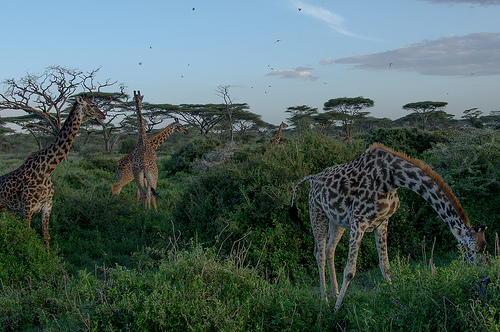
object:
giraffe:
[288, 139, 499, 314]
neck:
[401, 151, 474, 225]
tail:
[286, 173, 309, 210]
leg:
[370, 230, 397, 286]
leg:
[332, 223, 368, 311]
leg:
[324, 225, 345, 292]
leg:
[309, 222, 330, 299]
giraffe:
[109, 117, 189, 196]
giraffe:
[131, 88, 161, 211]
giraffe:
[1, 86, 128, 255]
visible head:
[75, 90, 108, 122]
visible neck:
[45, 109, 84, 167]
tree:
[1, 63, 128, 159]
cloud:
[319, 32, 499, 75]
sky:
[1, 2, 499, 82]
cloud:
[260, 64, 324, 92]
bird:
[273, 37, 286, 48]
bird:
[295, 4, 306, 17]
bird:
[188, 5, 198, 13]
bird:
[137, 60, 146, 69]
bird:
[147, 42, 160, 51]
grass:
[368, 258, 500, 330]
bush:
[0, 207, 88, 329]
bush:
[257, 129, 351, 276]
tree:
[323, 96, 375, 136]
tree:
[400, 98, 448, 131]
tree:
[212, 83, 238, 141]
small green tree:
[459, 106, 485, 125]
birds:
[245, 83, 260, 90]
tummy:
[321, 188, 351, 229]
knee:
[342, 268, 355, 281]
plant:
[138, 224, 289, 332]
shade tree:
[281, 105, 321, 132]